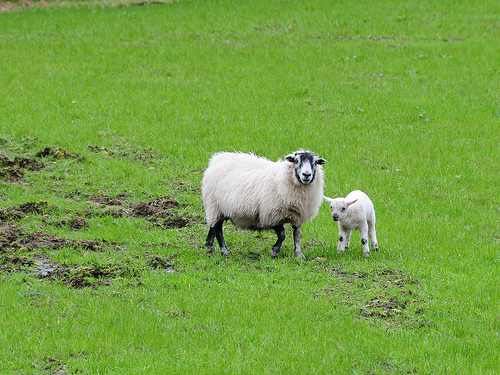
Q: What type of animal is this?
A: Sheep.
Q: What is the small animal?
A: Lamb.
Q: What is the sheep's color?
A: White.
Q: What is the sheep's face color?
A: Black and white.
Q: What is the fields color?
A: Green.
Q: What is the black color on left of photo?
A: Mud.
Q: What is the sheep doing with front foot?
A: Holding it up.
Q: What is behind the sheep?
A: Dark green grass field.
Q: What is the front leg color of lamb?
A: White with black spots on knees.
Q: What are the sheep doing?
A: Looking at camera.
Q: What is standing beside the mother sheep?
A: Baby.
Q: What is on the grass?
A: Patches of dirt.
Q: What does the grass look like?
A: Green.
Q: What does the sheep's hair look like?
A: Fluffy.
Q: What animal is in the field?
A: Sheep.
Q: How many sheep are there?
A: Two.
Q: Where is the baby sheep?
A: To the right of the adult.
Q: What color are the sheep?
A: White.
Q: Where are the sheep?
A: In a grassy field.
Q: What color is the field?
A: Green.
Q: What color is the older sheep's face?
A: Black and white.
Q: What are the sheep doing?
A: Standing and staring.